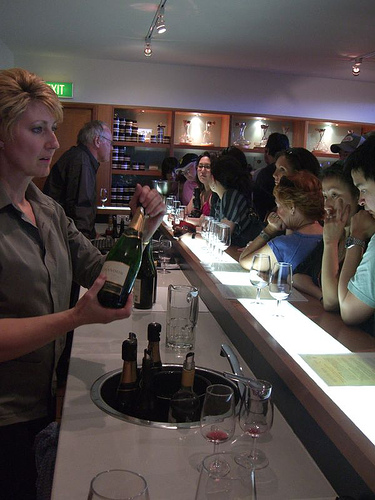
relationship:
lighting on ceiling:
[138, 1, 175, 62] [0, 3, 374, 91]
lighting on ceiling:
[339, 44, 373, 78] [0, 3, 374, 91]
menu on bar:
[292, 343, 374, 391] [158, 205, 374, 480]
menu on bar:
[215, 282, 314, 310] [158, 205, 374, 480]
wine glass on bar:
[234, 377, 274, 473] [48, 219, 351, 497]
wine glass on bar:
[195, 383, 237, 481] [48, 219, 351, 497]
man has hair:
[43, 121, 116, 241] [73, 117, 112, 147]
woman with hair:
[2, 66, 170, 499] [2, 67, 64, 144]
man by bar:
[43, 121, 116, 241] [158, 205, 374, 480]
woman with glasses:
[182, 149, 220, 222] [193, 163, 214, 173]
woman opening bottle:
[2, 66, 170, 499] [93, 197, 149, 307]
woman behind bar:
[2, 66, 170, 499] [158, 205, 374, 480]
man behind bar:
[43, 121, 116, 241] [158, 205, 374, 480]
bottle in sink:
[113, 340, 139, 417] [87, 354, 249, 432]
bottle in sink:
[167, 354, 198, 424] [87, 354, 249, 432]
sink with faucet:
[87, 354, 249, 432] [216, 343, 259, 414]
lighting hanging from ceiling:
[138, 1, 175, 62] [0, 3, 374, 91]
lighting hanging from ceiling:
[339, 44, 373, 78] [0, 3, 374, 91]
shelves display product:
[32, 101, 374, 242] [115, 119, 168, 143]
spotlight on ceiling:
[350, 60, 365, 78] [0, 3, 374, 91]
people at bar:
[260, 138, 374, 328] [158, 205, 374, 480]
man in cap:
[175, 151, 199, 206] [171, 151, 197, 175]